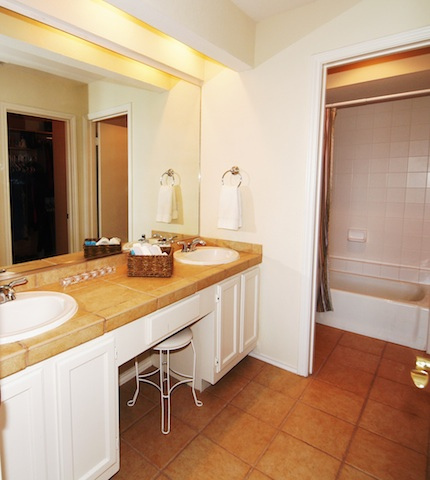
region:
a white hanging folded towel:
[217, 185, 242, 229]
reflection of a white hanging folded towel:
[155, 181, 177, 224]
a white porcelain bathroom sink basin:
[175, 246, 237, 263]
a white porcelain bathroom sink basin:
[0, 290, 76, 343]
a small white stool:
[127, 328, 204, 434]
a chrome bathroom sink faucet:
[175, 236, 207, 251]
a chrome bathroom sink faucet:
[0, 276, 28, 302]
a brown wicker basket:
[124, 245, 173, 276]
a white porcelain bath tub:
[317, 266, 428, 350]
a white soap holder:
[346, 225, 366, 242]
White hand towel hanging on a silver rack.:
[218, 184, 243, 231]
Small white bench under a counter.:
[128, 327, 202, 433]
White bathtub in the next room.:
[311, 268, 429, 353]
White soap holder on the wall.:
[345, 228, 368, 243]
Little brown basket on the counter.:
[128, 245, 174, 276]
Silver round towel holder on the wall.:
[220, 166, 243, 188]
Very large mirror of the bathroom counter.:
[0, 0, 200, 283]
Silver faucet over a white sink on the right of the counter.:
[189, 237, 206, 253]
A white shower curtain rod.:
[324, 88, 429, 108]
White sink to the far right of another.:
[172, 247, 240, 266]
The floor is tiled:
[105, 318, 424, 477]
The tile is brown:
[116, 307, 423, 476]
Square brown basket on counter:
[127, 240, 172, 275]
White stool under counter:
[126, 321, 205, 436]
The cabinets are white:
[12, 261, 258, 478]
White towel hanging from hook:
[214, 169, 249, 237]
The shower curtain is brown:
[311, 130, 338, 329]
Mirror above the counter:
[5, 8, 264, 372]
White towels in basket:
[127, 239, 173, 278]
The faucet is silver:
[173, 238, 206, 253]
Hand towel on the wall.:
[208, 159, 249, 238]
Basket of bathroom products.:
[122, 239, 176, 283]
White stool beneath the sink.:
[125, 318, 199, 439]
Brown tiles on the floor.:
[278, 375, 378, 476]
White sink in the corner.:
[172, 227, 243, 277]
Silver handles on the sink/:
[172, 233, 208, 255]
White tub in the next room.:
[328, 267, 426, 333]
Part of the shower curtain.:
[312, 161, 338, 318]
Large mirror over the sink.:
[16, 165, 130, 243]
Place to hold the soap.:
[340, 220, 371, 248]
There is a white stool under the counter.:
[129, 326, 202, 432]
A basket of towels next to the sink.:
[125, 242, 174, 277]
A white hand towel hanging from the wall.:
[218, 186, 241, 229]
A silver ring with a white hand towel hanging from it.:
[222, 166, 242, 186]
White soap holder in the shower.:
[346, 229, 366, 240]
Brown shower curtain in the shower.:
[316, 105, 330, 311]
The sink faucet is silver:
[175, 238, 206, 253]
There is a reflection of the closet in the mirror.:
[5, 109, 73, 263]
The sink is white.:
[172, 239, 239, 264]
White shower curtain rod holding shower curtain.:
[320, 88, 428, 107]